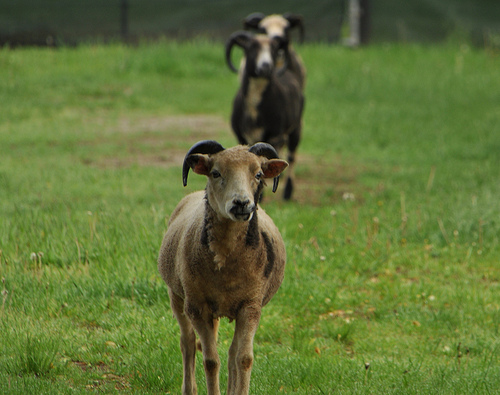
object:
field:
[1, 245, 124, 394]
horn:
[181, 139, 227, 186]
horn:
[221, 32, 251, 72]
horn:
[276, 35, 295, 69]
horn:
[245, 14, 265, 31]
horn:
[281, 11, 306, 46]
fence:
[3, 0, 498, 44]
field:
[307, 72, 492, 387]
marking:
[248, 74, 260, 140]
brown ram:
[157, 138, 288, 394]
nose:
[233, 197, 253, 207]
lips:
[231, 205, 252, 222]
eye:
[255, 171, 263, 183]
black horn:
[181, 138, 224, 185]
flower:
[330, 217, 442, 300]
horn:
[248, 142, 284, 193]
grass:
[377, 69, 496, 166]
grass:
[384, 179, 460, 257]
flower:
[328, 207, 340, 229]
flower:
[28, 251, 35, 266]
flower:
[34, 249, 44, 267]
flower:
[368, 214, 381, 236]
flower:
[342, 191, 355, 211]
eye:
[208, 167, 224, 180]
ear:
[259, 153, 291, 178]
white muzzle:
[221, 179, 253, 221]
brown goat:
[221, 25, 308, 201]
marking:
[250, 219, 277, 280]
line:
[113, 10, 148, 21]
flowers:
[0, 46, 495, 390]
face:
[242, 35, 282, 76]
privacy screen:
[0, 0, 500, 50]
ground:
[23, 41, 122, 73]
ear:
[186, 152, 215, 172]